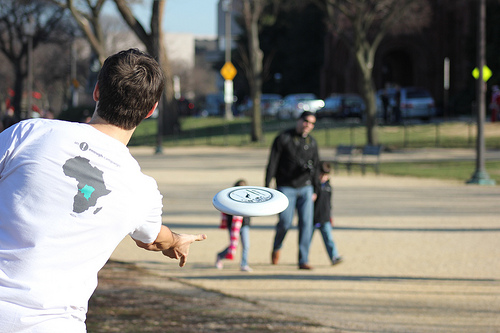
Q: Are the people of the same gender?
A: No, they are both male and female.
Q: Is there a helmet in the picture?
A: No, there are no helmets.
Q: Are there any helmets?
A: No, there are no helmets.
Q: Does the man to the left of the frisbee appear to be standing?
A: Yes, the man is standing.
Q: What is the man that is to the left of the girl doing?
A: The man is standing.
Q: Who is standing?
A: The man is standing.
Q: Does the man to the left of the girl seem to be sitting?
A: No, the man is standing.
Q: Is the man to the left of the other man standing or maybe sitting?
A: The man is standing.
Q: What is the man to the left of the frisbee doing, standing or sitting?
A: The man is standing.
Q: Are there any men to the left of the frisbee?
A: Yes, there is a man to the left of the frisbee.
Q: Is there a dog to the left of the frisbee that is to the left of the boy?
A: No, there is a man to the left of the frisbee.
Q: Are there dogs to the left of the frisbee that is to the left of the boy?
A: No, there is a man to the left of the frisbee.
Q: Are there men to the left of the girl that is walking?
A: Yes, there is a man to the left of the girl.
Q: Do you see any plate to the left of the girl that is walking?
A: No, there is a man to the left of the girl.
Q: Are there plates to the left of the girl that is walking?
A: No, there is a man to the left of the girl.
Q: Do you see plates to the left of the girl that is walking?
A: No, there is a man to the left of the girl.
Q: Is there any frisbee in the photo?
A: Yes, there is a frisbee.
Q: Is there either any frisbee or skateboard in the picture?
A: Yes, there is a frisbee.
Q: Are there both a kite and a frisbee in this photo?
A: No, there is a frisbee but no kites.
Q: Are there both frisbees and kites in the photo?
A: No, there is a frisbee but no kites.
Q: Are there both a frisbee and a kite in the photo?
A: No, there is a frisbee but no kites.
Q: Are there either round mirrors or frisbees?
A: Yes, there is a round frisbee.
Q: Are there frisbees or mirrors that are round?
A: Yes, the frisbee is round.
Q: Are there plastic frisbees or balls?
A: Yes, there is a plastic frisbee.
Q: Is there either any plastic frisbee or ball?
A: Yes, there is a plastic frisbee.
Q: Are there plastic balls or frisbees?
A: Yes, there is a plastic frisbee.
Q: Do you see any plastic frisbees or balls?
A: Yes, there is a plastic frisbee.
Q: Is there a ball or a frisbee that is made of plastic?
A: Yes, the frisbee is made of plastic.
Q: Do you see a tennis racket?
A: No, there are no rackets.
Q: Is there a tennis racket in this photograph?
A: No, there are no rackets.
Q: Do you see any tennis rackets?
A: No, there are no tennis rackets.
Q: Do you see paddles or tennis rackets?
A: No, there are no tennis rackets or paddles.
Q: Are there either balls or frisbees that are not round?
A: No, there is a frisbee but it is round.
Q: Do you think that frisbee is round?
A: Yes, the frisbee is round.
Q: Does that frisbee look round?
A: Yes, the frisbee is round.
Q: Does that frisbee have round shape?
A: Yes, the frisbee is round.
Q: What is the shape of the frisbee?
A: The frisbee is round.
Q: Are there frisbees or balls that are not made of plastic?
A: No, there is a frisbee but it is made of plastic.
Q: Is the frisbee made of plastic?
A: Yes, the frisbee is made of plastic.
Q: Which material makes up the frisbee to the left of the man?
A: The frisbee is made of plastic.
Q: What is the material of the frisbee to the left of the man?
A: The frisbee is made of plastic.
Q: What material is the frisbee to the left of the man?
A: The frisbee is made of plastic.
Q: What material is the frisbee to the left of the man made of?
A: The frisbee is made of plastic.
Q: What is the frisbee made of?
A: The frisbee is made of plastic.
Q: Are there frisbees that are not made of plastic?
A: No, there is a frisbee but it is made of plastic.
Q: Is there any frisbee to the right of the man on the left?
A: Yes, there is a frisbee to the right of the man.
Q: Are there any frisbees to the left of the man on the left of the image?
A: No, the frisbee is to the right of the man.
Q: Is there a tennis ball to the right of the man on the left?
A: No, there is a frisbee to the right of the man.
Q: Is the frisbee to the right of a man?
A: Yes, the frisbee is to the right of a man.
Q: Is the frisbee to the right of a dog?
A: No, the frisbee is to the right of a man.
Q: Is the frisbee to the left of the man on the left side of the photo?
A: No, the frisbee is to the right of the man.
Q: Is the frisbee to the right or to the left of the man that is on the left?
A: The frisbee is to the right of the man.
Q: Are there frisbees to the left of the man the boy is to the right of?
A: Yes, there is a frisbee to the left of the man.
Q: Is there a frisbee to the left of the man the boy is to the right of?
A: Yes, there is a frisbee to the left of the man.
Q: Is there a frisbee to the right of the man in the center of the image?
A: No, the frisbee is to the left of the man.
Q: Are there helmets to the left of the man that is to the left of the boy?
A: No, there is a frisbee to the left of the man.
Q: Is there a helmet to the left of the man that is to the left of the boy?
A: No, there is a frisbee to the left of the man.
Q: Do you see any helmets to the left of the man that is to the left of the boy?
A: No, there is a frisbee to the left of the man.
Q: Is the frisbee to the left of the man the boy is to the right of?
A: Yes, the frisbee is to the left of the man.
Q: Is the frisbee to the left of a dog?
A: No, the frisbee is to the left of the man.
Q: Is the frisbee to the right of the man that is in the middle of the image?
A: No, the frisbee is to the left of the man.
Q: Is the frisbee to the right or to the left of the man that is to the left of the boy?
A: The frisbee is to the left of the man.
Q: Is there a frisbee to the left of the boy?
A: Yes, there is a frisbee to the left of the boy.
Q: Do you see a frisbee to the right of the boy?
A: No, the frisbee is to the left of the boy.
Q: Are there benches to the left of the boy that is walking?
A: No, there is a frisbee to the left of the boy.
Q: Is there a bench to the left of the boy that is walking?
A: No, there is a frisbee to the left of the boy.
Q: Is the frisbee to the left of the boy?
A: Yes, the frisbee is to the left of the boy.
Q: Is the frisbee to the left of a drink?
A: No, the frisbee is to the left of the boy.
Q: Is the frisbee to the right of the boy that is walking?
A: No, the frisbee is to the left of the boy.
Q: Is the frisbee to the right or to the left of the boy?
A: The frisbee is to the left of the boy.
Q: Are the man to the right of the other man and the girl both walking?
A: Yes, both the man and the girl are walking.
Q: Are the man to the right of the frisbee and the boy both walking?
A: Yes, both the man and the boy are walking.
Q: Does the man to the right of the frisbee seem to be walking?
A: Yes, the man is walking.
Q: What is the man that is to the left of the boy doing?
A: The man is walking.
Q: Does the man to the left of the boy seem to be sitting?
A: No, the man is walking.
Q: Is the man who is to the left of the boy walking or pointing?
A: The man is walking.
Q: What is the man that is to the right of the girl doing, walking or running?
A: The man is walking.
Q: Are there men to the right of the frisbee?
A: Yes, there is a man to the right of the frisbee.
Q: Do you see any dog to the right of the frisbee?
A: No, there is a man to the right of the frisbee.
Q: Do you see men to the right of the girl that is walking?
A: Yes, there is a man to the right of the girl.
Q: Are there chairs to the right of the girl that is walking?
A: No, there is a man to the right of the girl.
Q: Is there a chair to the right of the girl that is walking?
A: No, there is a man to the right of the girl.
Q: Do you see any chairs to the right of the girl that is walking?
A: No, there is a man to the right of the girl.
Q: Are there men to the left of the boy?
A: Yes, there is a man to the left of the boy.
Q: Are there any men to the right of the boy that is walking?
A: No, the man is to the left of the boy.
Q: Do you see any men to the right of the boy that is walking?
A: No, the man is to the left of the boy.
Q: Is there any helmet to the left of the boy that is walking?
A: No, there is a man to the left of the boy.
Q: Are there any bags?
A: No, there are no bags.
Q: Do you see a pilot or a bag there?
A: No, there are no bags or pilots.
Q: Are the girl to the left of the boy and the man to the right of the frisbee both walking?
A: Yes, both the girl and the man are walking.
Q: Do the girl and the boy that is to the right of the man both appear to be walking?
A: Yes, both the girl and the boy are walking.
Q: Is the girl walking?
A: Yes, the girl is walking.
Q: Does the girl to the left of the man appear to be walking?
A: Yes, the girl is walking.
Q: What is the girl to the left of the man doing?
A: The girl is walking.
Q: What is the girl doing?
A: The girl is walking.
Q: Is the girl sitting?
A: No, the girl is walking.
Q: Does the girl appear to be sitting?
A: No, the girl is walking.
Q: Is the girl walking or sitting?
A: The girl is walking.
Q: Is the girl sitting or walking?
A: The girl is walking.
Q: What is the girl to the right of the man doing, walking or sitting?
A: The girl is walking.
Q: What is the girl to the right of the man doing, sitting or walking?
A: The girl is walking.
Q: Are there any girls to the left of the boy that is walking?
A: Yes, there is a girl to the left of the boy.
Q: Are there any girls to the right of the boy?
A: No, the girl is to the left of the boy.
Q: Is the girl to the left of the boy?
A: Yes, the girl is to the left of the boy.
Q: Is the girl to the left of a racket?
A: No, the girl is to the left of the boy.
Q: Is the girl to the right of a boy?
A: No, the girl is to the left of a boy.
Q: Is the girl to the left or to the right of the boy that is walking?
A: The girl is to the left of the boy.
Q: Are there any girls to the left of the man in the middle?
A: Yes, there is a girl to the left of the man.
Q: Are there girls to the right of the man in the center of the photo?
A: No, the girl is to the left of the man.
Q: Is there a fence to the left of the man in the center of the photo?
A: No, there is a girl to the left of the man.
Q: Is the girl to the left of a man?
A: Yes, the girl is to the left of a man.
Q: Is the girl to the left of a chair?
A: No, the girl is to the left of a man.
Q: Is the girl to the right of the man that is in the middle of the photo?
A: No, the girl is to the left of the man.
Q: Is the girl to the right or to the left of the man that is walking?
A: The girl is to the left of the man.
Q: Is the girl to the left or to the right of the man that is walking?
A: The girl is to the left of the man.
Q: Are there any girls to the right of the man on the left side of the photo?
A: Yes, there is a girl to the right of the man.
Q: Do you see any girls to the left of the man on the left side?
A: No, the girl is to the right of the man.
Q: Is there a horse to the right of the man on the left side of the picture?
A: No, there is a girl to the right of the man.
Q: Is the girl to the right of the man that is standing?
A: Yes, the girl is to the right of the man.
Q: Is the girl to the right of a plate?
A: No, the girl is to the right of the man.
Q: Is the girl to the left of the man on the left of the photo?
A: No, the girl is to the right of the man.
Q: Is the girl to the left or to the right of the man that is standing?
A: The girl is to the right of the man.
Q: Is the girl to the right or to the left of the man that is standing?
A: The girl is to the right of the man.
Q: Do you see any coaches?
A: No, there are no coaches.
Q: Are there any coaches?
A: No, there are no coaches.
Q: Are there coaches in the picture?
A: No, there are no coaches.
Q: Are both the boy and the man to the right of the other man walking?
A: Yes, both the boy and the man are walking.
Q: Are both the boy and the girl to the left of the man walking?
A: Yes, both the boy and the girl are walking.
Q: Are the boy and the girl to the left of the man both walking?
A: Yes, both the boy and the girl are walking.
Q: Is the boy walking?
A: Yes, the boy is walking.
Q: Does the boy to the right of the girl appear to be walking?
A: Yes, the boy is walking.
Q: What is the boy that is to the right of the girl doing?
A: The boy is walking.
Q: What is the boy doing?
A: The boy is walking.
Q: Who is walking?
A: The boy is walking.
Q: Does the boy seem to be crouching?
A: No, the boy is walking.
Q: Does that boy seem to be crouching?
A: No, the boy is walking.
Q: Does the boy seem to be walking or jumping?
A: The boy is walking.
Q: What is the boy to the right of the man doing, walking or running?
A: The boy is walking.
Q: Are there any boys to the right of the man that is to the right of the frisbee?
A: Yes, there is a boy to the right of the man.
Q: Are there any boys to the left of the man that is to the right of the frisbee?
A: No, the boy is to the right of the man.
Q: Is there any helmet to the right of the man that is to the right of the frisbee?
A: No, there is a boy to the right of the man.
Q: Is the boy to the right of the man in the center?
A: Yes, the boy is to the right of the man.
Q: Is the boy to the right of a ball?
A: No, the boy is to the right of the man.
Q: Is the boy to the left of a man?
A: No, the boy is to the right of a man.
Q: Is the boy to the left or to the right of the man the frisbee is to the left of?
A: The boy is to the right of the man.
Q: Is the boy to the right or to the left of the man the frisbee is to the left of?
A: The boy is to the right of the man.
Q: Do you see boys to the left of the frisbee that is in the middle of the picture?
A: No, the boy is to the right of the frisbee.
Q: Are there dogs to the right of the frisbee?
A: No, there is a boy to the right of the frisbee.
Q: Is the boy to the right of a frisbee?
A: Yes, the boy is to the right of a frisbee.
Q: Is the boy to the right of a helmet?
A: No, the boy is to the right of a frisbee.